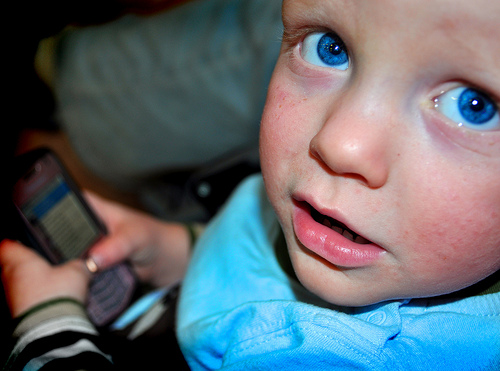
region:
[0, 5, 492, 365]
This is a child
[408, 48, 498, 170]
This is an eye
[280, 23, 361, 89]
This is an eye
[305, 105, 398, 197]
This is a nose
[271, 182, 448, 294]
This is a mouse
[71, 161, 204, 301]
This is a hand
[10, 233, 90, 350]
This is a hand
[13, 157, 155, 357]
This is a phone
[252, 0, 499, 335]
This is a face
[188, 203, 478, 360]
This is a jacket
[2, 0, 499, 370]
Young boy playing with cellphone.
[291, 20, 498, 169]
The child has blue eyes.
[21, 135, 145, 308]
The boy is holding a cellphone.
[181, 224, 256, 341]
The boy is wearing a blue shirt.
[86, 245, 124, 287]
Fingers on the cellphone screen.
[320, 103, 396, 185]
The kid has a nose.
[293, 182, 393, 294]
The kid mouth is open.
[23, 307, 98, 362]
The sleeves of the shirt has stripes.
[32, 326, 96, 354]
The stripes are white and black.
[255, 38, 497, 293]
The child is looking at the camera.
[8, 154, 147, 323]
Hands holding the cellphone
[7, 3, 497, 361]
little boyholding a phone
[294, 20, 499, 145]
two bright blue eyes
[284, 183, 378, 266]
mouth is slightly open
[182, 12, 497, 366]
looking over the shoulder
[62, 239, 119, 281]
thumbs resting on the keyboard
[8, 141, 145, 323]
small non-smart phone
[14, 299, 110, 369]
stripes on the sleeve of the shirt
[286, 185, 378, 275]
light pink lips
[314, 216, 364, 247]
teeth are barely visible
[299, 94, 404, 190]
small nose